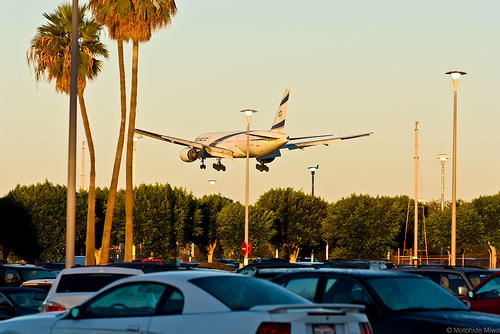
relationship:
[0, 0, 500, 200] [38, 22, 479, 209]
clouds in sky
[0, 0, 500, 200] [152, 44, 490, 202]
clouds in sky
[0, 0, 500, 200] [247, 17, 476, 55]
clouds in blue sky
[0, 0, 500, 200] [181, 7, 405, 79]
clouds in sky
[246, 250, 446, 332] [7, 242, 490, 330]
car in lot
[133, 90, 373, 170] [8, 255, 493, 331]
airplane landing behind parking lot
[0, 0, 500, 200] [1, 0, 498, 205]
clouds in sky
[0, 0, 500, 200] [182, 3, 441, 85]
clouds in sky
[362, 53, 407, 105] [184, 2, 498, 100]
clouds in sky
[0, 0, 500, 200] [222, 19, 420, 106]
clouds in sky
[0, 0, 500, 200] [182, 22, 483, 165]
clouds in sky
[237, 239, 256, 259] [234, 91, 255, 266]
sign on pole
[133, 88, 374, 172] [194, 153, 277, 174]
airplane with landing gear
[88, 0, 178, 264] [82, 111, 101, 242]
palmtrees with trunk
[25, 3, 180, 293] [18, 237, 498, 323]
palmtrees in lot